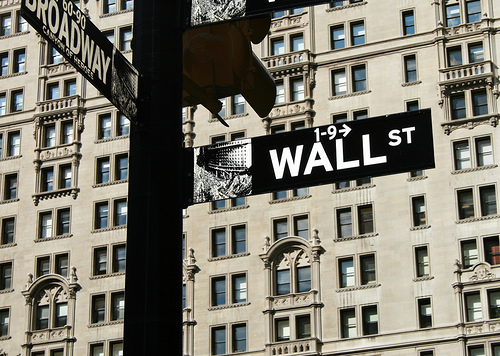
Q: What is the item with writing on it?
A: A street sign.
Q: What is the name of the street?
A: Wall St.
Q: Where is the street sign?
A: On a corner.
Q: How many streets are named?
A: Two.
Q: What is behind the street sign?
A: A building.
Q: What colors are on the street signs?
A: Black and white.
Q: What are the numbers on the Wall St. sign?
A: 1 and 9.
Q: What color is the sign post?
A: Black.